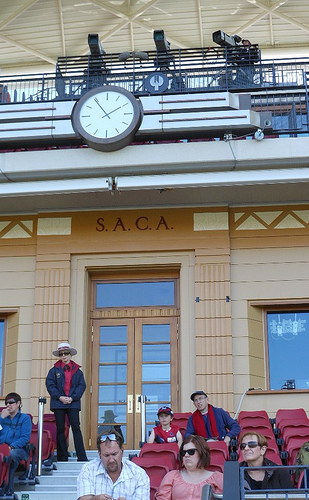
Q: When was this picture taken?
A: During the day.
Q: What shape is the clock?
A: A circle.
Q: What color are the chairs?
A: Red.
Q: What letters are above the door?
A: S.A.C.A.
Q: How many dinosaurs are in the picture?
A: Zero.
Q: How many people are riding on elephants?
A: Zero.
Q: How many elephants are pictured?
A: Zero.